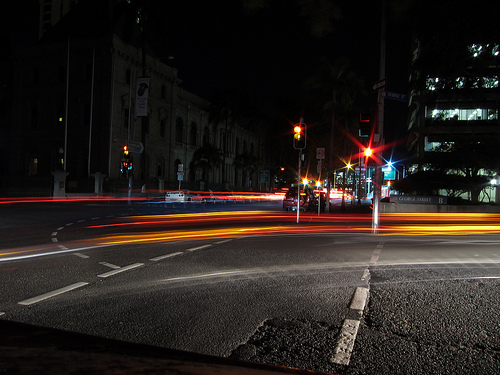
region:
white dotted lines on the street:
[20, 211, 388, 373]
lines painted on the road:
[17, 223, 400, 372]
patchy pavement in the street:
[240, 284, 493, 374]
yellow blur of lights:
[103, 202, 499, 247]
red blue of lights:
[5, 185, 285, 212]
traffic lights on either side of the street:
[113, 121, 301, 160]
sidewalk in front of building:
[370, 182, 474, 221]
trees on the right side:
[402, 124, 499, 215]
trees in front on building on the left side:
[181, 143, 276, 192]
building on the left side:
[80, 24, 292, 191]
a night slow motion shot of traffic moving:
[11, 18, 493, 350]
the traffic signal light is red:
[355, 140, 385, 172]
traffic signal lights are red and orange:
[117, 120, 309, 165]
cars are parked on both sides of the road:
[156, 184, 329, 215]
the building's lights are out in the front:
[66, 34, 278, 199]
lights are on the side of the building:
[23, 92, 71, 187]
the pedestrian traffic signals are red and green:
[113, 155, 137, 181]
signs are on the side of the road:
[169, 155, 187, 195]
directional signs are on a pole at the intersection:
[365, 66, 407, 133]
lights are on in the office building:
[400, 29, 497, 211]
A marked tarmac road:
[240, 282, 402, 371]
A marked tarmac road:
[347, 219, 416, 279]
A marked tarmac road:
[56, 243, 165, 307]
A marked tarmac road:
[33, 195, 102, 242]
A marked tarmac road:
[457, 230, 498, 319]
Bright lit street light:
[357, 138, 380, 165]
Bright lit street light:
[282, 114, 310, 153]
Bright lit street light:
[118, 141, 140, 171]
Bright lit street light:
[290, 166, 309, 191]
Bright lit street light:
[340, 156, 357, 182]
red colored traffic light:
[360, 147, 375, 158]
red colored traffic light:
[291, 125, 303, 132]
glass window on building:
[423, 73, 443, 90]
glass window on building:
[452, 75, 462, 85]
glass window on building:
[424, 104, 442, 121]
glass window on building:
[445, 104, 462, 124]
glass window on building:
[460, 110, 473, 122]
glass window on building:
[486, 109, 496, 119]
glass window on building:
[424, 137, 441, 151]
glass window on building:
[56, 107, 66, 127]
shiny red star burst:
[342, 123, 391, 178]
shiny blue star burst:
[375, 148, 406, 175]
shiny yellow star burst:
[336, 153, 357, 174]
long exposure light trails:
[2, 185, 499, 293]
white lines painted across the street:
[332, 219, 391, 372]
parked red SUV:
[280, 180, 318, 213]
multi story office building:
[396, 23, 498, 203]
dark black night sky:
[99, 0, 385, 177]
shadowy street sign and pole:
[172, 159, 189, 204]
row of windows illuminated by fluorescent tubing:
[419, 101, 499, 126]